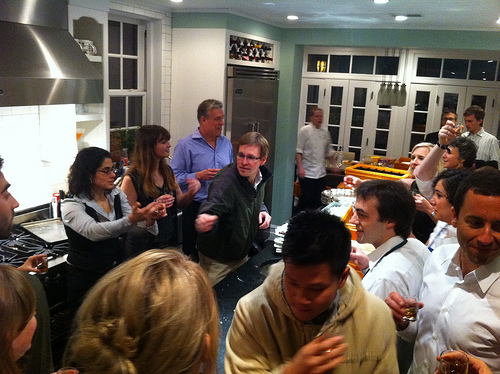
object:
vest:
[56, 191, 127, 272]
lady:
[59, 146, 175, 334]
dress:
[62, 183, 139, 334]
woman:
[424, 168, 472, 253]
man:
[192, 131, 272, 287]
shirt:
[171, 127, 234, 206]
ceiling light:
[394, 16, 408, 22]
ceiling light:
[286, 16, 298, 23]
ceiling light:
[171, 0, 186, 6]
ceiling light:
[373, 0, 389, 3]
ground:
[236, 247, 272, 293]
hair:
[282, 206, 350, 276]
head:
[279, 209, 352, 319]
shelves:
[76, 101, 106, 157]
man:
[412, 169, 499, 373]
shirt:
[361, 234, 433, 330]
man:
[347, 178, 430, 374]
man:
[458, 104, 500, 162]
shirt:
[461, 129, 500, 172]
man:
[223, 208, 396, 374]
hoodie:
[224, 259, 401, 374]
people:
[1, 97, 498, 371]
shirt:
[406, 243, 500, 374]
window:
[109, 9, 152, 157]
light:
[0, 104, 78, 164]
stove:
[0, 203, 182, 374]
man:
[169, 98, 237, 263]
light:
[286, 13, 298, 24]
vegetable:
[354, 165, 405, 176]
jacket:
[192, 163, 272, 263]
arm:
[201, 173, 236, 223]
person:
[414, 120, 475, 198]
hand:
[438, 119, 464, 145]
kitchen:
[0, 0, 499, 370]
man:
[384, 165, 499, 374]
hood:
[0, 0, 109, 106]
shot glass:
[404, 292, 420, 322]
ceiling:
[112, 0, 477, 25]